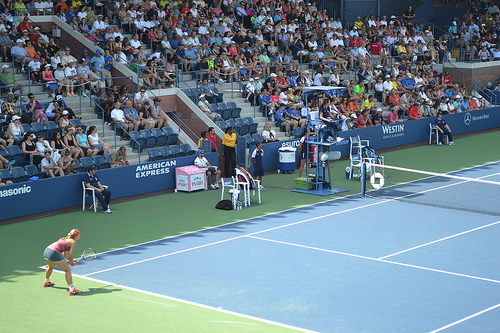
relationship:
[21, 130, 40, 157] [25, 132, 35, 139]
woman has glasses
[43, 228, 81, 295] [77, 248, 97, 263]
girl holds racket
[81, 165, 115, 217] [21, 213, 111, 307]
score keep watch tennis match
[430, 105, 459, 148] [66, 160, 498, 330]
score keep watch tennis court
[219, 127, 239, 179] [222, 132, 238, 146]
person wearing shirt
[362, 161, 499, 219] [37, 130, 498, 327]
net on court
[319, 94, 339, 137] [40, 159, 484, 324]
linesman next to court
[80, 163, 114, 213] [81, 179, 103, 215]
person in chair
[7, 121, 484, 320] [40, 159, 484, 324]
trim around court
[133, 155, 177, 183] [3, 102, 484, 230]
writing on wall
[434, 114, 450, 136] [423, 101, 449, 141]
man sitting in chair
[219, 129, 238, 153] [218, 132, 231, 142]
person in shirt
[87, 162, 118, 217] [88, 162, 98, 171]
man wears hat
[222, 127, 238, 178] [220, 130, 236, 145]
person wears yellow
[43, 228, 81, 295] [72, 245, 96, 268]
girl holding racket